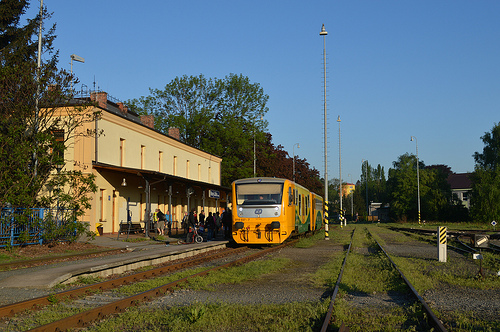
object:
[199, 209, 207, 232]
people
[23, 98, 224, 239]
station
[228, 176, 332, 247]
train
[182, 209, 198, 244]
person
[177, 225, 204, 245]
tricycle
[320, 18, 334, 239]
pole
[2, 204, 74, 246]
fence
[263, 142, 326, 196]
trees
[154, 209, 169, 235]
man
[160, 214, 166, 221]
backpack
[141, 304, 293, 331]
grass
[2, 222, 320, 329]
tracks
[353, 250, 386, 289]
grass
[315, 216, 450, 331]
tracks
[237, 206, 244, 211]
headlights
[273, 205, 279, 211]
headlights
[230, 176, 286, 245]
front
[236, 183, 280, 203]
glass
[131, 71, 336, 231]
group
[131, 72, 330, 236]
trees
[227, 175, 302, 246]
car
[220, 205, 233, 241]
passenger